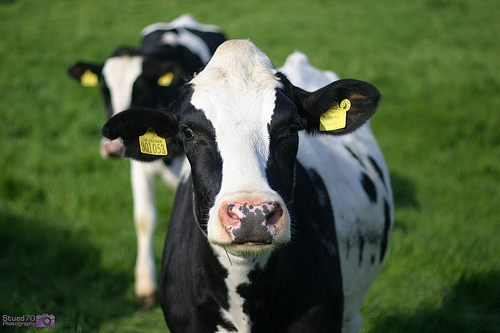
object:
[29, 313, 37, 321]
number 0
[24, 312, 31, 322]
number 7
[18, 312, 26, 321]
letter d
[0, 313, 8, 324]
letter s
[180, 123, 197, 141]
eye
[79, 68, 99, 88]
tag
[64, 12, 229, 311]
cow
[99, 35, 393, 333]
cow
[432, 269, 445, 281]
bad sentence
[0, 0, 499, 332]
day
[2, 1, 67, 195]
grass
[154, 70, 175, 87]
tag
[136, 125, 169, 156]
tag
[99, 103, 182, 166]
ear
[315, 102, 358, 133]
tags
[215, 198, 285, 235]
nose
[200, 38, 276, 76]
lump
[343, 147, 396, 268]
spots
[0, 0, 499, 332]
field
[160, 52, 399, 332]
snout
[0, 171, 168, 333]
shadow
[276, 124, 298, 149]
eye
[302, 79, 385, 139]
ear